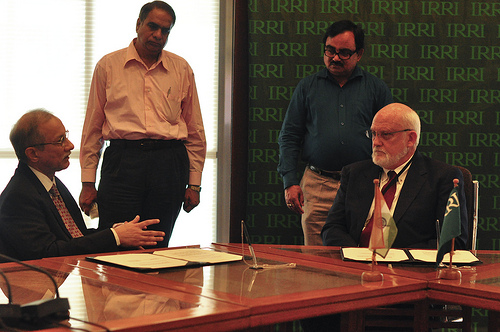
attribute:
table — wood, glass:
[4, 241, 479, 330]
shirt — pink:
[73, 38, 210, 192]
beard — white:
[370, 149, 410, 176]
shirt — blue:
[274, 58, 390, 193]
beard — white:
[365, 145, 413, 172]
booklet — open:
[78, 245, 254, 278]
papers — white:
[91, 248, 190, 277]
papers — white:
[153, 245, 243, 270]